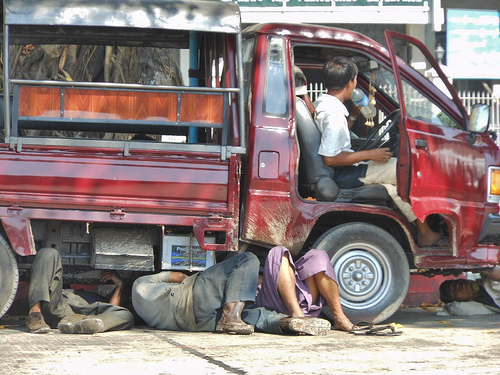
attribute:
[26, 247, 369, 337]
people — working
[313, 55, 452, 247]
man — sitting, drinking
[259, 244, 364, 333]
man — laying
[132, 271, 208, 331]
shirt — grey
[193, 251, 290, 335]
jeans — blue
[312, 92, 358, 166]
shirt — white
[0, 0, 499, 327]
truck — red, large, medium sized, rusted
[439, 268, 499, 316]
man — laying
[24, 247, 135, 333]
man — laying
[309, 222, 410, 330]
wheel — black, diry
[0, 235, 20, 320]
wheel — black, dirty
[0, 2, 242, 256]
truck bed — red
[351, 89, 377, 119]
bottle — plastic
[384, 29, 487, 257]
door — open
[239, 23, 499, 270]
truck cab — small, muddy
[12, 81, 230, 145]
panel — wooden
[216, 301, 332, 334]
boots — brown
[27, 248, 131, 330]
pants — grey